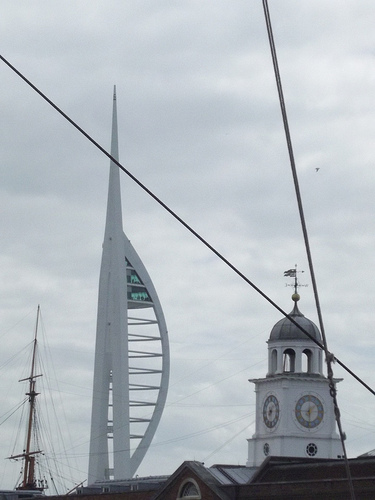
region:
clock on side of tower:
[291, 390, 325, 429]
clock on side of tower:
[256, 395, 280, 430]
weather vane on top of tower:
[278, 260, 307, 296]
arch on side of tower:
[295, 347, 313, 370]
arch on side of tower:
[279, 348, 294, 371]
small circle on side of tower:
[304, 443, 319, 455]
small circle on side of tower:
[261, 443, 271, 454]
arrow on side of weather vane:
[297, 268, 306, 274]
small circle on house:
[174, 478, 202, 496]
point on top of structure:
[102, 79, 124, 112]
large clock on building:
[251, 379, 359, 469]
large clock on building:
[244, 400, 341, 497]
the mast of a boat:
[16, 300, 63, 486]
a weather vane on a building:
[274, 261, 312, 292]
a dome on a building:
[268, 312, 324, 340]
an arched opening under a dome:
[300, 345, 315, 372]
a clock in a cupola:
[292, 387, 329, 430]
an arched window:
[174, 476, 202, 498]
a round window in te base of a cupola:
[305, 441, 319, 455]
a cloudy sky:
[2, 3, 373, 490]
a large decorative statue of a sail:
[90, 83, 173, 487]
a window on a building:
[102, 484, 111, 493]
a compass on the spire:
[282, 263, 307, 294]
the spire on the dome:
[275, 258, 313, 320]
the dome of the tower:
[263, 303, 323, 348]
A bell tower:
[230, 307, 348, 466]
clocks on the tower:
[259, 389, 330, 438]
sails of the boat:
[8, 297, 63, 494]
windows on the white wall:
[255, 436, 320, 459]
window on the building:
[171, 476, 201, 499]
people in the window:
[123, 263, 151, 303]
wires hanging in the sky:
[185, 361, 229, 452]